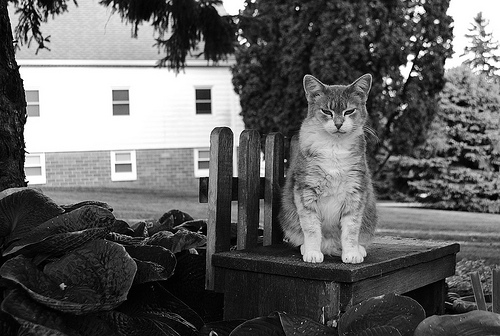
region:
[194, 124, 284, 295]
wooden fence like slats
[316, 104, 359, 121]
cats eyes looking at camera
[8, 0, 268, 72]
limbs hanging down from evergreen tree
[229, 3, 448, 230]
tree located behind cat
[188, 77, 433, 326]
cat sitting on wooden bench with slat back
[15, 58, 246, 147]
white shingle siding of house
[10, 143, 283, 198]
laid brick outer wall of home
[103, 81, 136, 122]
window on white home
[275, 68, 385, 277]
medium length haired white and gray cat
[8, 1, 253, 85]
roof of white home with branches in front of it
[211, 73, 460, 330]
cat sitting on a table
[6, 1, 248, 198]
white building in the background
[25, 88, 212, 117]
row of three windows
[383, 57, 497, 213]
pine tree in yard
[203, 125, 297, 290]
wooden picket fence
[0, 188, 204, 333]
leafy plant by tree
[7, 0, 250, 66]
roof on building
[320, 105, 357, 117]
slanted eyes on cat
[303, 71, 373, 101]
two ears on cat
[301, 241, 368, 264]
white paws on cat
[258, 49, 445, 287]
Cat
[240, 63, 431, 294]
Cat is sitting on the chair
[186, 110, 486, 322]
Chair is made of wood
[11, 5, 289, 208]
Building in the back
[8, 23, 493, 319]
This photo is black and white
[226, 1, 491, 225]
Trees in the back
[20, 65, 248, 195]
Multiple windows on the building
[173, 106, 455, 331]
Object is made of wood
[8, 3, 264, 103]
Tree branches handing in the corner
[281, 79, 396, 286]
The cat has multiple colors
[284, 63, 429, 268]
cat in black and white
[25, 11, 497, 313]
black and white photo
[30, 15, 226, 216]
house with six windows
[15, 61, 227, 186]
six windows on a house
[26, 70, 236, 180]
six windows in the background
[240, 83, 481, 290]
cat in black and white on a chair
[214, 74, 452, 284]
cat on a chair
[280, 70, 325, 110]
the ear on a cat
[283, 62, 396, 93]
two ears on a cat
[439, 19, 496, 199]
pine tree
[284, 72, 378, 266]
a small cat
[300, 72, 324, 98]
the ear of a cat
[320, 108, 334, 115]
the eye of a cat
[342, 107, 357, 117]
the eye of a cat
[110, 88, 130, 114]
an exterior window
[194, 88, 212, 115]
and exterior window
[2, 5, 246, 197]
a two story house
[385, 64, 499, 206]
a large tree in the distance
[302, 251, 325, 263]
the paw of a cat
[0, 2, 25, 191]
section of the trunk of a tree